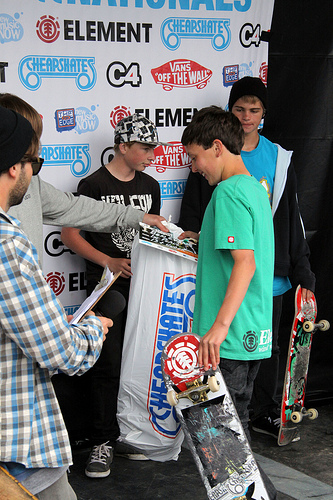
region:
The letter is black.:
[59, 17, 75, 45]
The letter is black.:
[73, 18, 85, 44]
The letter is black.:
[82, 17, 99, 43]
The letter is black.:
[95, 19, 116, 45]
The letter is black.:
[114, 19, 127, 42]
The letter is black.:
[125, 21, 142, 47]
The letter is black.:
[139, 18, 154, 45]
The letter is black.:
[152, 105, 164, 133]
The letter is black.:
[163, 103, 182, 132]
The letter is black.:
[66, 268, 80, 294]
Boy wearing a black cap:
[174, 73, 316, 441]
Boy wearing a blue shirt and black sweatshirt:
[175, 73, 317, 442]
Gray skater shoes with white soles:
[81, 438, 154, 479]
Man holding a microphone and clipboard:
[0, 107, 125, 499]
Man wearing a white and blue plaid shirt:
[0, 107, 114, 498]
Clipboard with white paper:
[66, 261, 122, 325]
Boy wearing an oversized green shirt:
[180, 103, 276, 498]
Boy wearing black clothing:
[59, 111, 174, 479]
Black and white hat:
[110, 112, 172, 148]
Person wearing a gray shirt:
[1, 91, 169, 278]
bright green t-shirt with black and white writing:
[193, 171, 273, 360]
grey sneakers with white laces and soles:
[82, 442, 151, 479]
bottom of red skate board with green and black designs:
[276, 284, 330, 450]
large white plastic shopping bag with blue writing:
[114, 219, 201, 460]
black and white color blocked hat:
[113, 114, 172, 147]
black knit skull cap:
[224, 72, 273, 113]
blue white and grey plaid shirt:
[0, 200, 104, 471]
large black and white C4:
[239, 22, 261, 51]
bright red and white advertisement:
[151, 58, 211, 93]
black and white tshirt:
[74, 168, 163, 285]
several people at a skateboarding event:
[3, 76, 321, 490]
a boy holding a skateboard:
[168, 107, 293, 493]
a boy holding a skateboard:
[214, 67, 331, 452]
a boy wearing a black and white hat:
[101, 108, 167, 186]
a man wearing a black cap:
[0, 103, 44, 223]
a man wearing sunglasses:
[2, 96, 51, 235]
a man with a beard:
[1, 104, 53, 226]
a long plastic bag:
[121, 219, 210, 460]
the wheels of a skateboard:
[301, 316, 330, 340]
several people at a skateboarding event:
[8, 70, 293, 492]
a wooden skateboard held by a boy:
[161, 330, 276, 497]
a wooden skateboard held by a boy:
[268, 275, 328, 467]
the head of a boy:
[178, 103, 242, 189]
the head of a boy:
[109, 105, 167, 183]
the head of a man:
[0, 107, 44, 212]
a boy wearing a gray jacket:
[171, 76, 323, 276]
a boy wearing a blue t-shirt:
[224, 82, 305, 189]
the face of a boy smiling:
[173, 106, 251, 184]